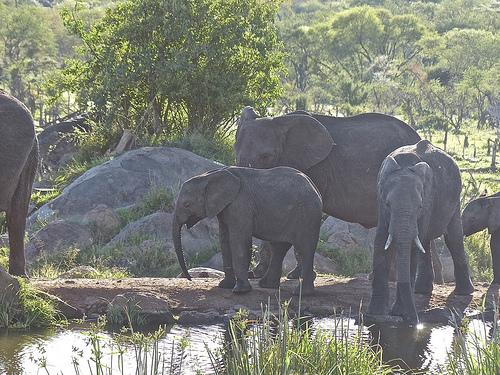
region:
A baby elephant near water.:
[166, 152, 317, 298]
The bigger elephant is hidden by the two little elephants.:
[225, 78, 425, 198]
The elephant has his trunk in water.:
[395, 236, 422, 331]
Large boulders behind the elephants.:
[30, 130, 202, 270]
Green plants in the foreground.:
[210, 303, 362, 373]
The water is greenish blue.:
[8, 330, 89, 350]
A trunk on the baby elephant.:
[165, 208, 200, 288]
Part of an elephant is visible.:
[2, 95, 59, 270]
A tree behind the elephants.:
[68, 0, 281, 145]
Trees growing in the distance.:
[311, 7, 437, 77]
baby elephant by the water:
[155, 156, 332, 310]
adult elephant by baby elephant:
[213, 102, 458, 312]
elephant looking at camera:
[356, 136, 468, 335]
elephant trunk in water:
[388, 263, 432, 339]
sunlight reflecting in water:
[3, 301, 498, 373]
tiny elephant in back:
[458, 186, 499, 302]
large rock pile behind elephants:
[18, 136, 470, 293]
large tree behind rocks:
[26, 1, 297, 168]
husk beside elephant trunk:
[408, 231, 432, 256]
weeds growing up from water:
[198, 288, 390, 371]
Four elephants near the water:
[128, 86, 499, 348]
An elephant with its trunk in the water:
[372, 130, 474, 347]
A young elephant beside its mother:
[129, 90, 383, 298]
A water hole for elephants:
[3, 298, 498, 366]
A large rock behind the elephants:
[23, 125, 374, 292]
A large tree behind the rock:
[65, 20, 296, 172]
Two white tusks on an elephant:
[365, 137, 479, 350]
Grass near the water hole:
[205, 296, 388, 373]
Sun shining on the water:
[326, 270, 481, 372]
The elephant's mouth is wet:
[155, 147, 333, 305]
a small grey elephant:
[167, 169, 318, 299]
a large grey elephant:
[362, 135, 472, 322]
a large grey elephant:
[226, 102, 432, 296]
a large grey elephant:
[0, 72, 44, 274]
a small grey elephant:
[456, 184, 498, 303]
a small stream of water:
[6, 306, 493, 369]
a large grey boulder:
[24, 145, 453, 281]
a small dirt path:
[26, 265, 483, 320]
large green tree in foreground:
[71, 0, 281, 152]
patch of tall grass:
[216, 292, 384, 372]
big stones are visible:
[88, 110, 269, 343]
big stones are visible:
[76, 131, 218, 276]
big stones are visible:
[48, 55, 236, 283]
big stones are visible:
[106, 196, 229, 335]